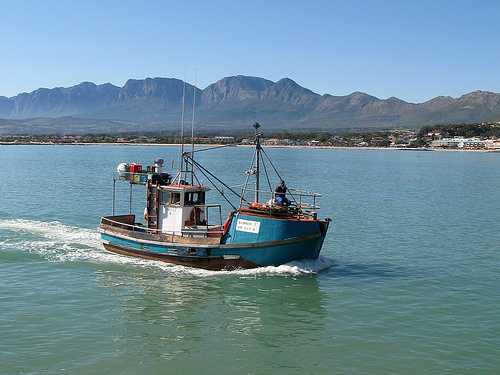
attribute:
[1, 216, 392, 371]
water — clear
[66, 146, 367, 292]
boat — sailing, blue, old, small, moving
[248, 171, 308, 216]
person — sitting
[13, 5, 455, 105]
sky — blue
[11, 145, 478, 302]
water — blue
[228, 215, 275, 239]
sign — white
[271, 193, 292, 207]
shorts — blue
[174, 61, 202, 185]
pole — gray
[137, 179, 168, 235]
ladder — red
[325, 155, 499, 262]
water — calm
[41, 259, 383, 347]
reflection — clear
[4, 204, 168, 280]
water — choppy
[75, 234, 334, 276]
base — black